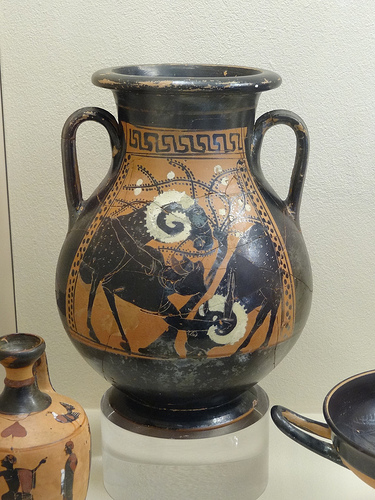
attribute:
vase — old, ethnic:
[4, 56, 336, 495]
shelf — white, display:
[0, 301, 373, 498]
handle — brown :
[60, 103, 125, 228]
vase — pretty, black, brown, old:
[53, 65, 314, 431]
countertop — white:
[75, 407, 337, 489]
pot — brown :
[47, 60, 329, 438]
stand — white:
[109, 396, 293, 492]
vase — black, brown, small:
[2, 334, 87, 493]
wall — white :
[307, 33, 346, 75]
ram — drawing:
[76, 190, 213, 367]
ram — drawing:
[181, 218, 284, 362]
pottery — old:
[52, 65, 315, 433]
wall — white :
[282, 23, 359, 93]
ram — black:
[193, 214, 292, 354]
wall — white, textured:
[315, 80, 366, 277]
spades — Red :
[1, 420, 28, 438]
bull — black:
[91, 215, 215, 358]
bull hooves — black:
[81, 324, 138, 359]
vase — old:
[4, 330, 102, 497]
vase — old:
[273, 363, 372, 499]